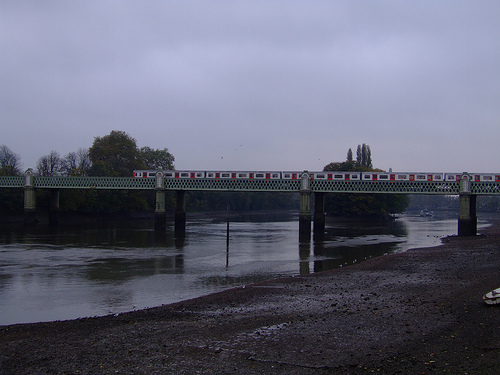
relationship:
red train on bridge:
[132, 170, 499, 182] [0, 172, 499, 271]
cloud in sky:
[0, 0, 500, 173] [0, 1, 498, 174]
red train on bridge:
[132, 170, 499, 182] [0, 177, 500, 229]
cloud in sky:
[161, 33, 445, 75] [0, 1, 498, 174]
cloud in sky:
[0, 0, 500, 173] [7, 5, 499, 122]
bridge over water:
[2, 167, 485, 236] [0, 200, 492, 331]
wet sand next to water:
[3, 225, 497, 367] [3, 225, 497, 322]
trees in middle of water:
[274, 130, 424, 257] [0, 200, 492, 331]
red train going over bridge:
[132, 170, 499, 182] [4, 170, 490, 204]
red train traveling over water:
[132, 170, 499, 182] [0, 200, 492, 331]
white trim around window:
[192, 167, 205, 179] [177, 167, 192, 181]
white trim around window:
[232, 168, 252, 181] [192, 168, 208, 178]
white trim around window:
[312, 170, 329, 183] [217, 167, 233, 177]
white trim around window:
[375, 170, 393, 182] [329, 167, 349, 180]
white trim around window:
[409, 172, 429, 182] [329, 167, 349, 180]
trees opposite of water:
[2, 132, 177, 212] [0, 200, 492, 331]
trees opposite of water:
[321, 143, 412, 217] [0, 200, 492, 331]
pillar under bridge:
[295, 190, 312, 249] [2, 163, 499, 213]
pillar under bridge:
[455, 192, 477, 237] [0, 166, 495, 208]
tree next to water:
[314, 159, 410, 216] [6, 210, 479, 332]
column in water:
[258, 199, 335, 261] [36, 226, 301, 284]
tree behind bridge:
[92, 127, 173, 179] [0, 169, 495, 241]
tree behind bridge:
[38, 140, 95, 170] [0, 169, 495, 241]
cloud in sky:
[0, 0, 500, 173] [363, 61, 488, 115]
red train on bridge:
[132, 170, 499, 182] [0, 169, 495, 241]